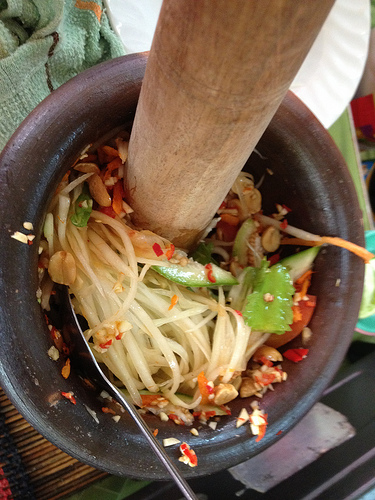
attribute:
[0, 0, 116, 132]
towel — green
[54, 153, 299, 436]
food — small, shredded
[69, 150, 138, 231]
vegetable — orange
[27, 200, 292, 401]
sprouts — white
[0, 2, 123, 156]
cloth — green, brown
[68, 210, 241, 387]
noodles — white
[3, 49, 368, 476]
bowl — part, brown, black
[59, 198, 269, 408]
vegetable — white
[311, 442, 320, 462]
table — part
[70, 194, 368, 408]
sprouts — white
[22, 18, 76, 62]
towel — green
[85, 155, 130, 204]
pepper seed — hot, red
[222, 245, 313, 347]
leaf — green, cilantro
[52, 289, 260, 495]
fork — part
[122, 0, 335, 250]
post — wooden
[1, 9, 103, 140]
towel — green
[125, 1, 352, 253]
pestle — marble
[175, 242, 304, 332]
vegetable — green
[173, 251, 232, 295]
lettuce — small, green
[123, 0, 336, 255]
stick — wooden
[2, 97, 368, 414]
cup — brown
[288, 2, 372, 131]
plate — white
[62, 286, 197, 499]
utensil — silver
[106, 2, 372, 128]
paper plate — white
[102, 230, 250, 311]
vegetables — different